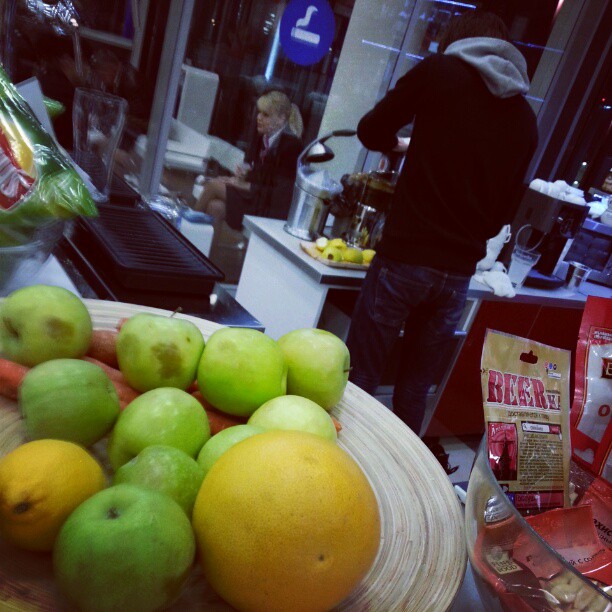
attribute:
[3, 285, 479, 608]
dish — round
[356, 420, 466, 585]
design — swirl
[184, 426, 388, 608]
orange — ripened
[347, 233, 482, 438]
jeans — blue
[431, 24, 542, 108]
hood — gray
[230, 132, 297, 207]
suit — business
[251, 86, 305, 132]
hair — blonde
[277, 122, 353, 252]
juicer — stainless, steel, fruit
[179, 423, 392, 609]
grapefruit — large, yellow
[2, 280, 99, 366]
apple — green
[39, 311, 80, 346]
bruise — brown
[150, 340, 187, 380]
bruise — brown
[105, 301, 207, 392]
apple — green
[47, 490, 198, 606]
apple — green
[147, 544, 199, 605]
bruise — brown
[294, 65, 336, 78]
sign — round and blue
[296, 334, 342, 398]
apple — green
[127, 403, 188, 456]
apple — green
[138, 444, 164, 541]
apple — green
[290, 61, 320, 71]
sign — round, blue and white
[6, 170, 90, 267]
bowl — clear